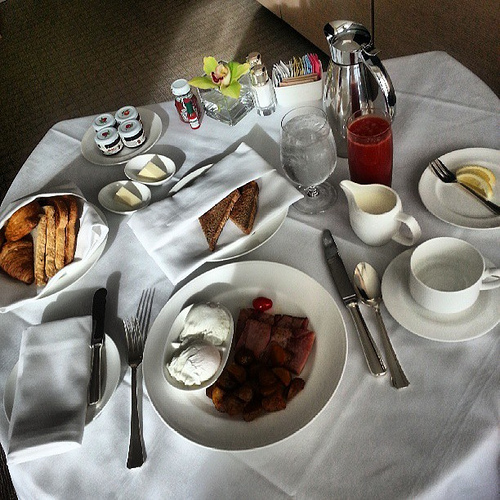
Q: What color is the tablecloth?
A: White.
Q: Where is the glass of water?
A: On the table.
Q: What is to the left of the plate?
A: Fork.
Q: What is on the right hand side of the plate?
A: Knife.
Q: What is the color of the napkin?
A: White.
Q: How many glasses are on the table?
A: Two.